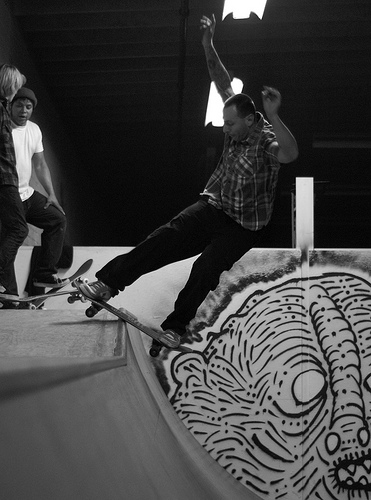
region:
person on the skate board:
[79, 253, 193, 354]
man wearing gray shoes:
[81, 275, 117, 306]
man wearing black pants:
[98, 190, 228, 332]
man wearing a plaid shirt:
[213, 125, 273, 224]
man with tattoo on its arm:
[206, 38, 241, 103]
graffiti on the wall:
[246, 282, 368, 433]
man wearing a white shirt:
[14, 129, 41, 207]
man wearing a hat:
[15, 83, 35, 101]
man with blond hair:
[3, 69, 18, 85]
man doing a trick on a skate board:
[73, 250, 200, 367]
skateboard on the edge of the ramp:
[76, 273, 178, 355]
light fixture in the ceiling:
[211, 59, 240, 143]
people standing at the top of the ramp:
[4, 51, 69, 324]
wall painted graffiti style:
[233, 275, 370, 483]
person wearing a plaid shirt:
[216, 130, 289, 233]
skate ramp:
[24, 324, 219, 433]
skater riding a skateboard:
[95, 32, 282, 357]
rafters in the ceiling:
[49, 21, 139, 137]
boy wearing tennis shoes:
[76, 280, 118, 300]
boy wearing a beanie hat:
[15, 85, 35, 98]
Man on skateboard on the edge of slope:
[65, 9, 300, 357]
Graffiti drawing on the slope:
[160, 256, 368, 498]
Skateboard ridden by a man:
[68, 283, 197, 355]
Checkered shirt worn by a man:
[202, 108, 276, 230]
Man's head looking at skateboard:
[217, 94, 257, 142]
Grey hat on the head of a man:
[8, 85, 38, 106]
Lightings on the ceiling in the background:
[203, 73, 244, 132]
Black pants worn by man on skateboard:
[92, 194, 265, 338]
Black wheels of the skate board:
[80, 301, 105, 317]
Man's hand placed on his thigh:
[41, 192, 68, 217]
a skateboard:
[106, 302, 157, 338]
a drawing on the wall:
[219, 278, 369, 487]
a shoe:
[37, 273, 67, 286]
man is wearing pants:
[147, 230, 207, 254]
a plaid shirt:
[218, 157, 269, 212]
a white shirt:
[16, 146, 30, 171]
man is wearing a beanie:
[19, 87, 34, 98]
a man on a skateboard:
[196, 11, 292, 271]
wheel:
[76, 294, 87, 303]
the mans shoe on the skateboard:
[160, 330, 179, 349]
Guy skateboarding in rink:
[50, 8, 310, 350]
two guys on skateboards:
[0, 66, 107, 314]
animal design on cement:
[164, 258, 369, 496]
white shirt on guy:
[9, 122, 51, 202]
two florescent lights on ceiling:
[176, 1, 274, 133]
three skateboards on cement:
[0, 254, 200, 370]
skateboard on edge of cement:
[63, 267, 197, 369]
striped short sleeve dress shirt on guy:
[205, 108, 291, 234]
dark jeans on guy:
[93, 191, 266, 340]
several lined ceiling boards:
[65, 23, 171, 147]